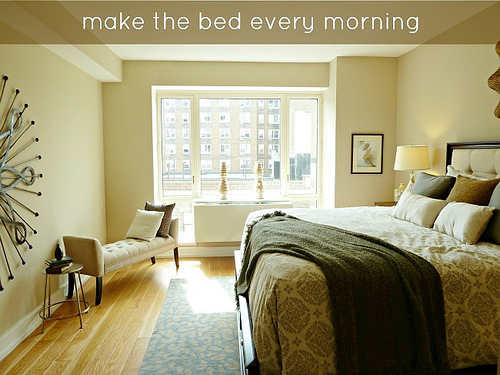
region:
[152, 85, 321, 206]
large bedroom window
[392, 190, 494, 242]
two rectangular throw pillows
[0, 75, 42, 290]
large metal wall decor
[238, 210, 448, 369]
dark folded blanket on the ground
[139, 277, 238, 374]
decorative area rug on the ground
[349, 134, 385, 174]
framed wall art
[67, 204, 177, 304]
sitting bench with two pillows on it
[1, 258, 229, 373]
light hardwood floors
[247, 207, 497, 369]
bedspread has a pattern on it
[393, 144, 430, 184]
bedside lamp is on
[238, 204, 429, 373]
A blanket hanging from a bed.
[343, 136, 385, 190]
A picture hanging from a wall.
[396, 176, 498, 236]
Pillows are displayed on a bed.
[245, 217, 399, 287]
A blanket is draped on a bed.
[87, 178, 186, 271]
a chair standing near a wall.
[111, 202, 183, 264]
Pillows sit on a chair.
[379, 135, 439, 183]
a lamp is lit near a bed.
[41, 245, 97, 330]
a table is standing near a chair.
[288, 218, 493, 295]
A comforter is covering a bed.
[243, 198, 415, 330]
a blanket is ontop of a comforter.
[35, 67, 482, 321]
an expensive bedroom in a hotel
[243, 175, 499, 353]
the bed is very well decorated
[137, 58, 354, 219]
the view is of a hotel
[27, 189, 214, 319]
there is an ottoman in the hotel room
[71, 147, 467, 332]
this bedroom is part of a five star hotel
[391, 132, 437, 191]
a light on the stand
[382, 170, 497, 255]
pillows on the bed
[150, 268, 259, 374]
a rug on the floor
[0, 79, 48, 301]
a decorative wall piece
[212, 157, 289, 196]
two candle standsiin the shot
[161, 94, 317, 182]
window in the room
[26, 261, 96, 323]
table near the wall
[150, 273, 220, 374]
rug on the floor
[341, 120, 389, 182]
image on the wall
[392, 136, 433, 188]
lamp on the table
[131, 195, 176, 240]
pillows on the couch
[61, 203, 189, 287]
couch near the window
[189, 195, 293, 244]
unit for heat and air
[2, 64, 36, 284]
artwork on the wall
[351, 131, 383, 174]
Art picture on wall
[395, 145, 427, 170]
White lamp shade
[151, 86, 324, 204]
Window with two decorative small lamps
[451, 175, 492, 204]
Red throw pillow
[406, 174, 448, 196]
Green throw pillow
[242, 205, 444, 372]
Green blanket on bed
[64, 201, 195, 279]
White day bench with two throw pillows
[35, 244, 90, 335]
Stool with book and pottery on top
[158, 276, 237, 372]
Blue rug on floor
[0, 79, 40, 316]
Large art on wall